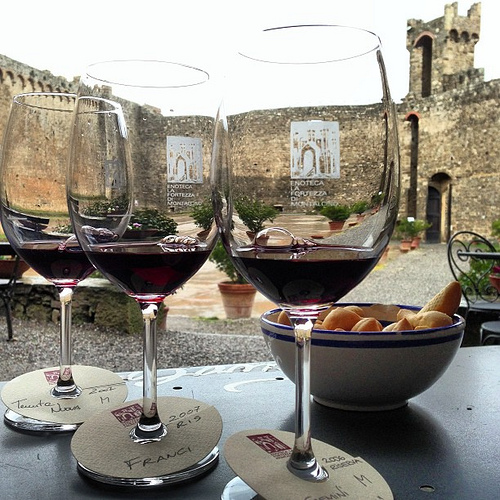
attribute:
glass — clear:
[211, 23, 401, 498]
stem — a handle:
[288, 311, 321, 472]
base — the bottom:
[221, 461, 389, 500]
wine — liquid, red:
[230, 253, 382, 304]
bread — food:
[277, 282, 464, 329]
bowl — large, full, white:
[258, 303, 465, 413]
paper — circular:
[70, 397, 222, 477]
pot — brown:
[218, 280, 255, 320]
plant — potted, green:
[190, 195, 265, 280]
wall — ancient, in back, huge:
[385, 0, 500, 248]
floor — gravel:
[335, 243, 467, 305]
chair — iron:
[446, 230, 498, 328]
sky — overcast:
[3, 0, 500, 117]